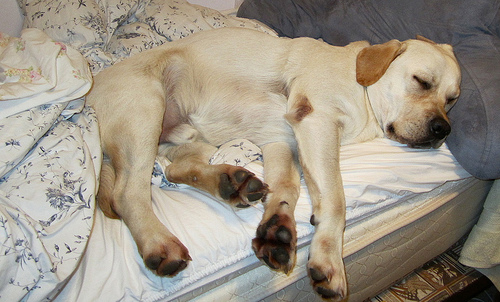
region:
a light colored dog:
[67, 23, 464, 298]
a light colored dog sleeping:
[85, 27, 465, 297]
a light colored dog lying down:
[71, 30, 457, 295]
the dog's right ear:
[351, 37, 406, 85]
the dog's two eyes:
[412, 68, 464, 109]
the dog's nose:
[427, 117, 450, 141]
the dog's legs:
[94, 100, 354, 300]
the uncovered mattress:
[152, 172, 496, 299]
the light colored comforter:
[8, 131, 79, 243]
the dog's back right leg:
[92, 97, 191, 278]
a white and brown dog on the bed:
[0, 2, 495, 297]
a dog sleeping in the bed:
[86, 25, 462, 300]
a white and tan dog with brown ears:
[87, 24, 462, 297]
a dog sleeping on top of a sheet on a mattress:
[140, 162, 346, 298]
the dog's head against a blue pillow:
[355, 0, 461, 148]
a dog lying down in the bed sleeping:
[80, 25, 460, 300]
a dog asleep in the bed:
[5, 1, 495, 296]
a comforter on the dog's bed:
[1, 120, 97, 300]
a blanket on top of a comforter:
[0, 28, 93, 122]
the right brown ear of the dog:
[355, 39, 400, 86]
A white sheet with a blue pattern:
[0, 103, 124, 300]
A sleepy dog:
[79, 7, 461, 295]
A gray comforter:
[231, 3, 496, 181]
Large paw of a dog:
[247, 213, 297, 278]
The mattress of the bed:
[2, 52, 487, 299]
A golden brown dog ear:
[353, 36, 405, 91]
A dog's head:
[352, 32, 465, 155]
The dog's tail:
[89, 153, 124, 227]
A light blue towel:
[457, 166, 498, 289]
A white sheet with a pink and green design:
[0, 21, 93, 106]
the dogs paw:
[251, 224, 296, 272]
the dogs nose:
[430, 115, 448, 137]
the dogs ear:
[356, 45, 388, 82]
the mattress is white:
[357, 221, 414, 280]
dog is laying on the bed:
[89, 30, 455, 279]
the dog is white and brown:
[86, 22, 461, 263]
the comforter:
[1, 98, 88, 285]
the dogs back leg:
[117, 121, 152, 281]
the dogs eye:
[412, 74, 433, 91]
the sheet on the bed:
[349, 152, 434, 192]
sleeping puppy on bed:
[78, 25, 461, 298]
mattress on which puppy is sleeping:
[73, 138, 488, 300]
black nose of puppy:
[427, 115, 452, 140]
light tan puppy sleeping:
[87, 25, 464, 300]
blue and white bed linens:
[9, 0, 124, 300]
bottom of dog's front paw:
[255, 217, 297, 273]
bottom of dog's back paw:
[214, 163, 271, 210]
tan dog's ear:
[354, 36, 404, 87]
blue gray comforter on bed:
[245, 3, 498, 41]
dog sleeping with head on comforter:
[85, 25, 462, 300]